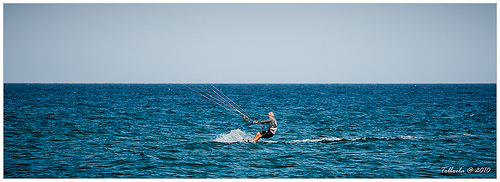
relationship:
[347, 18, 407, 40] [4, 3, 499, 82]
clouds in blue sky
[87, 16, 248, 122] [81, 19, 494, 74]
strings in sky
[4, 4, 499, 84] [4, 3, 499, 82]
clouds in blue sky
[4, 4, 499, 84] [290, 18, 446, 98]
clouds in sky